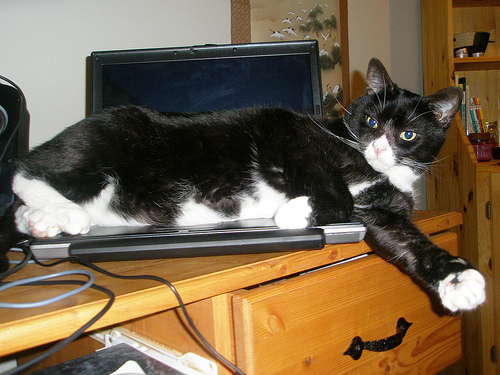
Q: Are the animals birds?
A: No, there are both birds and cats.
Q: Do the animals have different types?
A: Yes, they are birds and cats.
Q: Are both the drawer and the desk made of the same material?
A: Yes, both the drawer and the desk are made of wood.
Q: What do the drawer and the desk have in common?
A: The material, both the drawer and the desk are wooden.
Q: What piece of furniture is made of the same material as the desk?
A: The drawer is made of the same material as the desk.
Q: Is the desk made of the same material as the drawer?
A: Yes, both the desk and the drawer are made of wood.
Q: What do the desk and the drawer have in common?
A: The material, both the desk and the drawer are wooden.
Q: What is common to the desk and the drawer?
A: The material, both the desk and the drawer are wooden.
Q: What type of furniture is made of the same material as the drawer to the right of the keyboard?
A: The desk is made of the same material as the drawer.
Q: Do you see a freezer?
A: No, there are no refrigerators.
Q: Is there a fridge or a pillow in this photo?
A: No, there are no refrigerators or pillows.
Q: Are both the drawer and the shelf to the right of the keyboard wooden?
A: Yes, both the drawer and the shelf are wooden.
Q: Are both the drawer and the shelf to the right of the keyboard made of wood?
A: Yes, both the drawer and the shelf are made of wood.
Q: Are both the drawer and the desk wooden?
A: Yes, both the drawer and the desk are wooden.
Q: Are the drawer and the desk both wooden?
A: Yes, both the drawer and the desk are wooden.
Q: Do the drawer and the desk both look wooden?
A: Yes, both the drawer and the desk are wooden.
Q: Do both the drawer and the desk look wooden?
A: Yes, both the drawer and the desk are wooden.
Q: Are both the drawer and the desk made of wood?
A: Yes, both the drawer and the desk are made of wood.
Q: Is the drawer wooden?
A: Yes, the drawer is wooden.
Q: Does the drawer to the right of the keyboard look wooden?
A: Yes, the drawer is wooden.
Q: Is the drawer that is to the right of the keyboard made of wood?
A: Yes, the drawer is made of wood.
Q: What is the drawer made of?
A: The drawer is made of wood.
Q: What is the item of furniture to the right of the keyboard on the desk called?
A: The piece of furniture is a drawer.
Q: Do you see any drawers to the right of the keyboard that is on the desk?
A: Yes, there is a drawer to the right of the keyboard.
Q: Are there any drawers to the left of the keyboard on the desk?
A: No, the drawer is to the right of the keyboard.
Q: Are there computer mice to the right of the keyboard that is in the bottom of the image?
A: No, there is a drawer to the right of the keyboard.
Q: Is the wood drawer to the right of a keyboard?
A: Yes, the drawer is to the right of a keyboard.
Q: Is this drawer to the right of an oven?
A: No, the drawer is to the right of a keyboard.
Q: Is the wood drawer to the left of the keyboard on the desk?
A: No, the drawer is to the right of the keyboard.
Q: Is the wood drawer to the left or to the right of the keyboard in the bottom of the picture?
A: The drawer is to the right of the keyboard.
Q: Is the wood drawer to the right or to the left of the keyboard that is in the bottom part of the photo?
A: The drawer is to the right of the keyboard.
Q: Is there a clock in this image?
A: No, there are no clocks.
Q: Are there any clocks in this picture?
A: No, there are no clocks.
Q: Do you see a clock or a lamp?
A: No, there are no clocks or lamps.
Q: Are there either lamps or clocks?
A: No, there are no clocks or lamps.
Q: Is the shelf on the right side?
A: Yes, the shelf is on the right of the image.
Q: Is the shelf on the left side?
A: No, the shelf is on the right of the image.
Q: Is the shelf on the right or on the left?
A: The shelf is on the right of the image.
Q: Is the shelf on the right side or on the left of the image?
A: The shelf is on the right of the image.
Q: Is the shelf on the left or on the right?
A: The shelf is on the right of the image.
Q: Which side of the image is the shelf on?
A: The shelf is on the right of the image.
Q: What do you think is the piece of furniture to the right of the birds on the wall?
A: The piece of furniture is a shelf.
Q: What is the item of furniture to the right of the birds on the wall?
A: The piece of furniture is a shelf.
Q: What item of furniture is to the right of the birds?
A: The piece of furniture is a shelf.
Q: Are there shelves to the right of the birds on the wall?
A: Yes, there is a shelf to the right of the birds.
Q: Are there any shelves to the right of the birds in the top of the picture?
A: Yes, there is a shelf to the right of the birds.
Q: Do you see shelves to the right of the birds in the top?
A: Yes, there is a shelf to the right of the birds.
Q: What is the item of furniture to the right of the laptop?
A: The piece of furniture is a shelf.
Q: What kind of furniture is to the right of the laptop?
A: The piece of furniture is a shelf.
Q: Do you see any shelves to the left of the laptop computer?
A: No, the shelf is to the right of the laptop computer.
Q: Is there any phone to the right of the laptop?
A: No, there is a shelf to the right of the laptop.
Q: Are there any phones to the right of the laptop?
A: No, there is a shelf to the right of the laptop.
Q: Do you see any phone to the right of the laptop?
A: No, there is a shelf to the right of the laptop.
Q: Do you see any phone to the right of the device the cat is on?
A: No, there is a shelf to the right of the laptop.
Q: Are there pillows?
A: No, there are no pillows.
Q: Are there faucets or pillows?
A: No, there are no pillows or faucets.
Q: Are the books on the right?
A: Yes, the books are on the right of the image.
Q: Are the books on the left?
A: No, the books are on the right of the image.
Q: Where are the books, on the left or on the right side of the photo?
A: The books are on the right of the image.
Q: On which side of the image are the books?
A: The books are on the right of the image.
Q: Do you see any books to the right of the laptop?
A: Yes, there are books to the right of the laptop.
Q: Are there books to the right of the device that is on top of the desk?
A: Yes, there are books to the right of the laptop.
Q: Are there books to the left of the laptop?
A: No, the books are to the right of the laptop.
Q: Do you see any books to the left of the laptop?
A: No, the books are to the right of the laptop.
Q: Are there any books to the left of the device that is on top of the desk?
A: No, the books are to the right of the laptop.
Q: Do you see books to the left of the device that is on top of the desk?
A: No, the books are to the right of the laptop.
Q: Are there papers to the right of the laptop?
A: No, there are books to the right of the laptop.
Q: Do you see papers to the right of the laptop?
A: No, there are books to the right of the laptop.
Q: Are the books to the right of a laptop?
A: Yes, the books are to the right of a laptop.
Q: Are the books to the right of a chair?
A: No, the books are to the right of a laptop.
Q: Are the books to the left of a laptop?
A: No, the books are to the right of a laptop.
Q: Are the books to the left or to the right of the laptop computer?
A: The books are to the right of the laptop computer.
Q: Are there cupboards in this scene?
A: No, there are no cupboards.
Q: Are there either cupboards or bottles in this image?
A: No, there are no cupboards or bottles.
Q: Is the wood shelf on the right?
A: Yes, the shelf is on the right of the image.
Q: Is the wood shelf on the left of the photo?
A: No, the shelf is on the right of the image.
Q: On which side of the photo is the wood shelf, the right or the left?
A: The shelf is on the right of the image.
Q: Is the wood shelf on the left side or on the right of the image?
A: The shelf is on the right of the image.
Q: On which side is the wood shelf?
A: The shelf is on the right of the image.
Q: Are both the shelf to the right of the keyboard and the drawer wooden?
A: Yes, both the shelf and the drawer are wooden.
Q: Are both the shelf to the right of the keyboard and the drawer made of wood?
A: Yes, both the shelf and the drawer are made of wood.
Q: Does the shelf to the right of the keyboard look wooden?
A: Yes, the shelf is wooden.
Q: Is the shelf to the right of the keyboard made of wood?
A: Yes, the shelf is made of wood.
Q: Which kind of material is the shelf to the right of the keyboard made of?
A: The shelf is made of wood.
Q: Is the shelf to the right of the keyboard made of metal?
A: No, the shelf is made of wood.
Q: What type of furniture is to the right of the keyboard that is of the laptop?
A: The piece of furniture is a shelf.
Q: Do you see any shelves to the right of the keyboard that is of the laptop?
A: Yes, there is a shelf to the right of the keyboard.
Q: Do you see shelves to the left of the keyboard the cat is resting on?
A: No, the shelf is to the right of the keyboard.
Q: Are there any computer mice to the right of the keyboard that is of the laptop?
A: No, there is a shelf to the right of the keyboard.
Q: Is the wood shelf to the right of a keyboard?
A: Yes, the shelf is to the right of a keyboard.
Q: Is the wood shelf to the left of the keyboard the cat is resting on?
A: No, the shelf is to the right of the keyboard.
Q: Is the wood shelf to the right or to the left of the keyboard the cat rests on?
A: The shelf is to the right of the keyboard.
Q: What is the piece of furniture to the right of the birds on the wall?
A: The piece of furniture is a shelf.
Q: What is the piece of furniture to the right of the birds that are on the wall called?
A: The piece of furniture is a shelf.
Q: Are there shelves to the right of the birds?
A: Yes, there is a shelf to the right of the birds.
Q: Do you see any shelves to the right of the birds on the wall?
A: Yes, there is a shelf to the right of the birds.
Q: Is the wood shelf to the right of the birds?
A: Yes, the shelf is to the right of the birds.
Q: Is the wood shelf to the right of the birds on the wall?
A: Yes, the shelf is to the right of the birds.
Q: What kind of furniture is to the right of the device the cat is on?
A: The piece of furniture is a shelf.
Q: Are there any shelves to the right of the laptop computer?
A: Yes, there is a shelf to the right of the laptop computer.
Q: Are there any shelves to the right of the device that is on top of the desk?
A: Yes, there is a shelf to the right of the laptop computer.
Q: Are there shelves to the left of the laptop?
A: No, the shelf is to the right of the laptop.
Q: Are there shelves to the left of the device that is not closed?
A: No, the shelf is to the right of the laptop.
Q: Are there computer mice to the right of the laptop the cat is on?
A: No, there is a shelf to the right of the laptop.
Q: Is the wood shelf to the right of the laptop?
A: Yes, the shelf is to the right of the laptop.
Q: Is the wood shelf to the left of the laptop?
A: No, the shelf is to the right of the laptop.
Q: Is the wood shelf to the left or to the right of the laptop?
A: The shelf is to the right of the laptop.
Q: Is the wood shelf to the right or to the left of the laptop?
A: The shelf is to the right of the laptop.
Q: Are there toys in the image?
A: No, there are no toys.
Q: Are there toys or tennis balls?
A: No, there are no toys or tennis balls.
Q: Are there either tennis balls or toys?
A: No, there are no toys or tennis balls.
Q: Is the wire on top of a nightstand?
A: No, the wire is on top of a desk.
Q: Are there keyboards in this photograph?
A: Yes, there is a keyboard.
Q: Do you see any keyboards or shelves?
A: Yes, there is a keyboard.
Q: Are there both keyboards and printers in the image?
A: No, there is a keyboard but no printers.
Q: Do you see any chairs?
A: No, there are no chairs.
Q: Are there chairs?
A: No, there are no chairs.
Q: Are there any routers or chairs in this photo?
A: No, there are no chairs or routers.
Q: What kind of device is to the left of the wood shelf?
A: The device is a keyboard.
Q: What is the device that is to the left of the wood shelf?
A: The device is a keyboard.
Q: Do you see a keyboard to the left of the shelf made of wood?
A: Yes, there is a keyboard to the left of the shelf.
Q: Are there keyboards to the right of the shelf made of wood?
A: No, the keyboard is to the left of the shelf.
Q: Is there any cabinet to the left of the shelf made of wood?
A: No, there is a keyboard to the left of the shelf.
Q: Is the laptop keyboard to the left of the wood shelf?
A: Yes, the keyboard is to the left of the shelf.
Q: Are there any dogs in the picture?
A: No, there are no dogs.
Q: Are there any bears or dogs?
A: No, there are no dogs or bears.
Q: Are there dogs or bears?
A: No, there are no dogs or bears.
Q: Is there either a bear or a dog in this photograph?
A: No, there are no dogs or bears.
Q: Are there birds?
A: Yes, there are birds.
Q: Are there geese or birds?
A: Yes, there are birds.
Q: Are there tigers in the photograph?
A: No, there are no tigers.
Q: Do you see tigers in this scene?
A: No, there are no tigers.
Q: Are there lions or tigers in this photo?
A: No, there are no tigers or lions.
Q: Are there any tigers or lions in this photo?
A: No, there are no tigers or lions.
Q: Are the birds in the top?
A: Yes, the birds are in the top of the image.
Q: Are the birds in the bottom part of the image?
A: No, the birds are in the top of the image.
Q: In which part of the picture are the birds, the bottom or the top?
A: The birds are in the top of the image.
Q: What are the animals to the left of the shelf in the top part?
A: The animals are birds.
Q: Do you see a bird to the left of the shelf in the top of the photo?
A: Yes, there are birds to the left of the shelf.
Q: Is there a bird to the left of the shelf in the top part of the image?
A: Yes, there are birds to the left of the shelf.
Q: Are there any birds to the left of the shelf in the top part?
A: Yes, there are birds to the left of the shelf.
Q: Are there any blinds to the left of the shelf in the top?
A: No, there are birds to the left of the shelf.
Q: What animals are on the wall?
A: The animals are birds.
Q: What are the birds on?
A: The birds are on the wall.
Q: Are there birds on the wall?
A: Yes, there are birds on the wall.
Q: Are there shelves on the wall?
A: No, there are birds on the wall.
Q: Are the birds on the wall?
A: Yes, the birds are on the wall.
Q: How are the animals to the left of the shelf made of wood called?
A: The animals are birds.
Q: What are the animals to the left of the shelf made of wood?
A: The animals are birds.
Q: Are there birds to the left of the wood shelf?
A: Yes, there are birds to the left of the shelf.